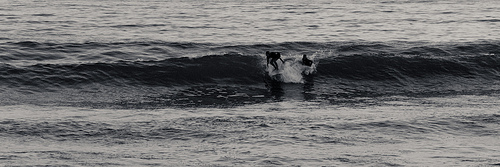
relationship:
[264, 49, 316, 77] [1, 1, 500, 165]
surfers in water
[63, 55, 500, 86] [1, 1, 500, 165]
wave in water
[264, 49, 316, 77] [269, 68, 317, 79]
surfers on surfboards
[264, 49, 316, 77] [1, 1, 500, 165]
surfers on water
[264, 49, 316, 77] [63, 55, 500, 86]
surfers on wave